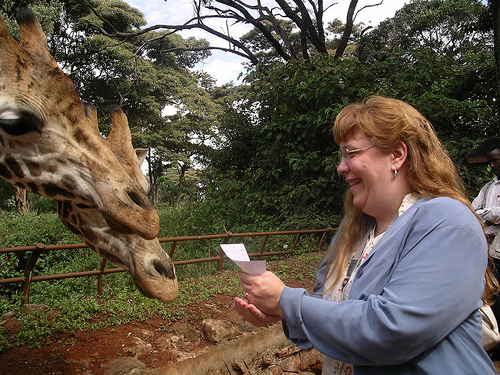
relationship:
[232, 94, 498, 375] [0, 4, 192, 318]
woman feeding giraffes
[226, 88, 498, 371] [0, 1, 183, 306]
woman feeding giraffe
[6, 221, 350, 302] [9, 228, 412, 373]
fence on ground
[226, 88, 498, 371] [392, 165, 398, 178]
woman wearing earring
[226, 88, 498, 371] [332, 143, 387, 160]
woman wearing glasses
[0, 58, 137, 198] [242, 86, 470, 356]
giraffe eating from woman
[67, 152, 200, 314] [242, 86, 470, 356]
giraffe eating from woman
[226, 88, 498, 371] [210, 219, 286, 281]
woman holding paper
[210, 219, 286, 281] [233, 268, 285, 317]
paper in hand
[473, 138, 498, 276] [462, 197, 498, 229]
man with arms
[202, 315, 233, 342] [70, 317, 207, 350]
rock in dirt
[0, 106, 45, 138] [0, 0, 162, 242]
eye of giraffe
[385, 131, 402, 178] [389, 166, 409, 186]
ear with earring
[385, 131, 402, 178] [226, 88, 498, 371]
ear of woman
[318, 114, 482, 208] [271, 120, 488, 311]
face of woman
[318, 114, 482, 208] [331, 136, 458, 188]
face with glasses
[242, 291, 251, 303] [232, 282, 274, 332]
ring on finger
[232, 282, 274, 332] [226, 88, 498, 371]
finger of woman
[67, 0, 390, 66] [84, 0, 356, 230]
branches from tall tree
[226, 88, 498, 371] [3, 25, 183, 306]
woman in front of giraffes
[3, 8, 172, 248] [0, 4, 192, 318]
heads of giraffes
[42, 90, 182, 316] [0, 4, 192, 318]
heads of giraffes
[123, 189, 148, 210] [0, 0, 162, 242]
nostril of giraffe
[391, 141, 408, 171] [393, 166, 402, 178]
ear with earring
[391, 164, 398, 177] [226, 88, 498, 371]
earring of woman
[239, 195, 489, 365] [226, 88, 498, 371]
arm of woman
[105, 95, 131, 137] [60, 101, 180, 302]
horn of giraffe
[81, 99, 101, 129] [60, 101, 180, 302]
horn of giraffe